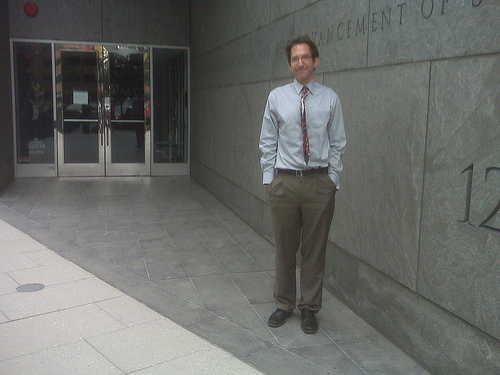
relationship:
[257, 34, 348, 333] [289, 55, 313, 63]
man wearing eye glasses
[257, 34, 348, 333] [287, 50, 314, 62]
man wearing glasses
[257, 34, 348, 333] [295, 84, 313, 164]
man wearing tie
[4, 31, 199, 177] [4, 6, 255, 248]
door on front of building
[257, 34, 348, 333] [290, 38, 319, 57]
man with hair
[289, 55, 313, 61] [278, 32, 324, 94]
eye glasses sitting on face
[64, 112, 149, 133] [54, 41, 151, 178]
rails on door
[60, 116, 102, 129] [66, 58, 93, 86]
rail behind glass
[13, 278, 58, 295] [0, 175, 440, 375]
grate on top of flooring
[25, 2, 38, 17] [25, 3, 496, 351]
alarm on side of building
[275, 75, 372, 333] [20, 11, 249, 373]
man outside of building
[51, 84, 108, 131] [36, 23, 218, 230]
sign hanging on door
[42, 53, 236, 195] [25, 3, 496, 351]
doors on building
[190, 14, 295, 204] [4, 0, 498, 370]
stones on building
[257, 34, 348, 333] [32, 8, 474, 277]
man standing next to office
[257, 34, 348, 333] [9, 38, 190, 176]
man in front of office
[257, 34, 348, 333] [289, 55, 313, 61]
man wearing eye glasses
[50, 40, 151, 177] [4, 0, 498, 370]
door on building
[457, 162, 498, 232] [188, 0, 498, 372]
number on wall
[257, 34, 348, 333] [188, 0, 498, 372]
man standing by wall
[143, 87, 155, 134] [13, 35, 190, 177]
reflection in door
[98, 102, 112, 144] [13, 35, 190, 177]
reflection in door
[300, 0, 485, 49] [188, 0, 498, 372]
writing on wall